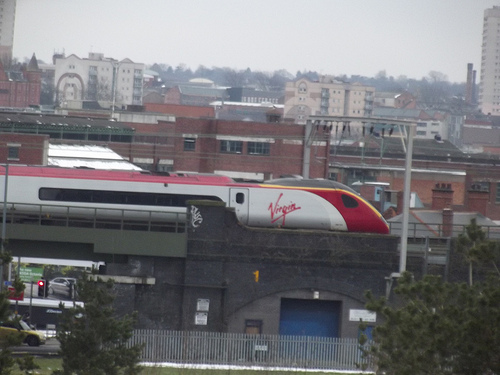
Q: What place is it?
A: It is a city.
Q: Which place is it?
A: It is a city.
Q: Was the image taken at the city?
A: Yes, it was taken in the city.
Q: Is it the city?
A: Yes, it is the city.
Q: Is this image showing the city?
A: Yes, it is showing the city.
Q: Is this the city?
A: Yes, it is the city.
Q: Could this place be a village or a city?
A: It is a city.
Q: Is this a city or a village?
A: It is a city.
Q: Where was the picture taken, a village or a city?
A: It was taken at a city.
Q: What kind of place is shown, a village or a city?
A: It is a city.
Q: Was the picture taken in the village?
A: No, the picture was taken in the city.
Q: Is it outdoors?
A: Yes, it is outdoors.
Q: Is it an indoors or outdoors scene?
A: It is outdoors.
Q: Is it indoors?
A: No, it is outdoors.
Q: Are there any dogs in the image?
A: No, there are no dogs.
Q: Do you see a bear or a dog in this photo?
A: No, there are no dogs or bears.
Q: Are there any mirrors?
A: No, there are no mirrors.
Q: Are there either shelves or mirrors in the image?
A: No, there are no mirrors or shelves.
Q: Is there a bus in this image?
A: No, there are no buses.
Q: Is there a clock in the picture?
A: No, there are no clocks.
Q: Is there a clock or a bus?
A: No, there are no clocks or buses.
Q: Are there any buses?
A: No, there are no buses.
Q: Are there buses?
A: No, there are no buses.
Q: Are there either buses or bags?
A: No, there are no buses or bags.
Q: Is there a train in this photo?
A: Yes, there is a train.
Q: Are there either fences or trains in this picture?
A: Yes, there is a train.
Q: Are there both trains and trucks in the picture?
A: No, there is a train but no trucks.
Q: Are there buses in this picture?
A: No, there are no buses.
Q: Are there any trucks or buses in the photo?
A: No, there are no buses or trucks.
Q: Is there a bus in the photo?
A: No, there are no buses.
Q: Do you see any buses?
A: No, there are no buses.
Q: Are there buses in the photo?
A: No, there are no buses.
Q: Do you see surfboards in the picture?
A: No, there are no surfboards.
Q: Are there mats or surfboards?
A: No, there are no surfboards or mats.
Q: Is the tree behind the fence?
A: Yes, the tree is behind the fence.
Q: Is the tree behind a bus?
A: No, the tree is behind the fence.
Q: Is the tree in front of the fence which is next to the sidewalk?
A: No, the tree is behind the fence.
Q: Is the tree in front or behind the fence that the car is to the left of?
A: The tree is behind the fence.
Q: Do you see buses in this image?
A: No, there are no buses.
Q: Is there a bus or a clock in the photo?
A: No, there are no buses or clocks.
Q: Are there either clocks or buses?
A: No, there are no buses or clocks.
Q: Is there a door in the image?
A: Yes, there are doors.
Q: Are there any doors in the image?
A: Yes, there are doors.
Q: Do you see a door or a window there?
A: Yes, there are doors.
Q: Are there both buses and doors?
A: No, there are doors but no buses.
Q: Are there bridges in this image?
A: Yes, there is a bridge.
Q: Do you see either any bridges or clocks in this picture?
A: Yes, there is a bridge.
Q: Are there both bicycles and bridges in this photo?
A: No, there is a bridge but no bikes.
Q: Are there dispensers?
A: No, there are no dispensers.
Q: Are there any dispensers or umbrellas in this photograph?
A: No, there are no dispensers or umbrellas.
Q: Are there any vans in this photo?
A: No, there are no vans.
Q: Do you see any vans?
A: No, there are no vans.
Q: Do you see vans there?
A: No, there are no vans.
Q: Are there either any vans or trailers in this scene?
A: No, there are no vans or trailers.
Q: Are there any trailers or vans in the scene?
A: No, there are no vans or trailers.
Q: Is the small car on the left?
A: Yes, the car is on the left of the image.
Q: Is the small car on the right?
A: No, the car is on the left of the image.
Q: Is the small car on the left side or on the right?
A: The car is on the left of the image.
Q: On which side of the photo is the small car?
A: The car is on the left of the image.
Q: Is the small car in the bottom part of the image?
A: Yes, the car is in the bottom of the image.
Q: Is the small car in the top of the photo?
A: No, the car is in the bottom of the image.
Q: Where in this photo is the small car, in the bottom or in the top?
A: The car is in the bottom of the image.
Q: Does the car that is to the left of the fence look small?
A: Yes, the car is small.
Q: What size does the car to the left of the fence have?
A: The car has small size.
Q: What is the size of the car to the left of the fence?
A: The car is small.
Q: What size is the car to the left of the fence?
A: The car is small.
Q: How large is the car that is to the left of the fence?
A: The car is small.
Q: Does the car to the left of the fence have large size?
A: No, the car is small.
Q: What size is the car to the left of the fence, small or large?
A: The car is small.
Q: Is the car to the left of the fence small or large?
A: The car is small.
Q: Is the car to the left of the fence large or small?
A: The car is small.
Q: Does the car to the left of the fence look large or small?
A: The car is small.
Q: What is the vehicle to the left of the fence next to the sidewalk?
A: The vehicle is a car.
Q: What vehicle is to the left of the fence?
A: The vehicle is a car.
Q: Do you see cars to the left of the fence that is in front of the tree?
A: Yes, there is a car to the left of the fence.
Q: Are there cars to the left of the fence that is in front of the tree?
A: Yes, there is a car to the left of the fence.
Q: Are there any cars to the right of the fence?
A: No, the car is to the left of the fence.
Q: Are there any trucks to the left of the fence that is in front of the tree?
A: No, there is a car to the left of the fence.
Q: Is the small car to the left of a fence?
A: Yes, the car is to the left of a fence.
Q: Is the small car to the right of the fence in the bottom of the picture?
A: No, the car is to the left of the fence.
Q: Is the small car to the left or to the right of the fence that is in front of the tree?
A: The car is to the left of the fence.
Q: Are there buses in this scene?
A: No, there are no buses.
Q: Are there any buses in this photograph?
A: No, there are no buses.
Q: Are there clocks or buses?
A: No, there are no buses or clocks.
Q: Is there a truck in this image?
A: No, there are no trucks.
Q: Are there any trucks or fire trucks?
A: No, there are no trucks or fire trucks.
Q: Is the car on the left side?
A: Yes, the car is on the left of the image.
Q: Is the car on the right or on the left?
A: The car is on the left of the image.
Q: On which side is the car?
A: The car is on the left of the image.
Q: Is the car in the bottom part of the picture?
A: Yes, the car is in the bottom of the image.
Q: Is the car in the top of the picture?
A: No, the car is in the bottom of the image.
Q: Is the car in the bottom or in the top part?
A: The car is in the bottom of the image.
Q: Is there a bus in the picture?
A: No, there are no buses.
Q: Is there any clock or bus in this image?
A: No, there are no buses or clocks.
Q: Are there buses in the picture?
A: No, there are no buses.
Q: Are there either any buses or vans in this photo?
A: No, there are no buses or vans.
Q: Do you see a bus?
A: No, there are no buses.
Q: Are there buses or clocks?
A: No, there are no buses or clocks.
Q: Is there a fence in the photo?
A: Yes, there is a fence.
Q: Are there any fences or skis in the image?
A: Yes, there is a fence.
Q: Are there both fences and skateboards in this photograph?
A: No, there is a fence but no skateboards.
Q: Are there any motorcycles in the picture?
A: No, there are no motorcycles.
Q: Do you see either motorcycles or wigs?
A: No, there are no motorcycles or wigs.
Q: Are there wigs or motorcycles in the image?
A: No, there are no motorcycles or wigs.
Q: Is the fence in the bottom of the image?
A: Yes, the fence is in the bottom of the image.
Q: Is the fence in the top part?
A: No, the fence is in the bottom of the image.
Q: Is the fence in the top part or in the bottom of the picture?
A: The fence is in the bottom of the image.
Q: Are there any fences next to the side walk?
A: Yes, there is a fence next to the side walk.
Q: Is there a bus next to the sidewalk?
A: No, there is a fence next to the sidewalk.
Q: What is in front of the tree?
A: The fence is in front of the tree.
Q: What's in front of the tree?
A: The fence is in front of the tree.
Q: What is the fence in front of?
A: The fence is in front of the tree.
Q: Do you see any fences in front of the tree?
A: Yes, there is a fence in front of the tree.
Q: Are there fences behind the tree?
A: No, the fence is in front of the tree.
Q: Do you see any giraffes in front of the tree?
A: No, there is a fence in front of the tree.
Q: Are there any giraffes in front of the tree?
A: No, there is a fence in front of the tree.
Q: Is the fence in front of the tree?
A: Yes, the fence is in front of the tree.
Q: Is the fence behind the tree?
A: No, the fence is in front of the tree.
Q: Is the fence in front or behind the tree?
A: The fence is in front of the tree.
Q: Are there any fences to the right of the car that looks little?
A: Yes, there is a fence to the right of the car.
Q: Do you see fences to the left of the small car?
A: No, the fence is to the right of the car.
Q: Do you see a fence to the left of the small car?
A: No, the fence is to the right of the car.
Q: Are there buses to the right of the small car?
A: No, there is a fence to the right of the car.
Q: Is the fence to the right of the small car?
A: Yes, the fence is to the right of the car.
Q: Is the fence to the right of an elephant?
A: No, the fence is to the right of the car.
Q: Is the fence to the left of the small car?
A: No, the fence is to the right of the car.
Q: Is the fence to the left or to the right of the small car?
A: The fence is to the right of the car.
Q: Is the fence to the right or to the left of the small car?
A: The fence is to the right of the car.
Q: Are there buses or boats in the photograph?
A: No, there are no buses or boats.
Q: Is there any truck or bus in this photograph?
A: No, there are no buses or trucks.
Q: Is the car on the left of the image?
A: Yes, the car is on the left of the image.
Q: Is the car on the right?
A: No, the car is on the left of the image.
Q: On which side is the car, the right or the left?
A: The car is on the left of the image.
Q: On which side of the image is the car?
A: The car is on the left of the image.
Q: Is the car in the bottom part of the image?
A: Yes, the car is in the bottom of the image.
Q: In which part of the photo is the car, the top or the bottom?
A: The car is in the bottom of the image.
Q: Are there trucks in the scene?
A: No, there are no trucks.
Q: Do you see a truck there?
A: No, there are no trucks.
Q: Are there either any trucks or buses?
A: No, there are no trucks or buses.